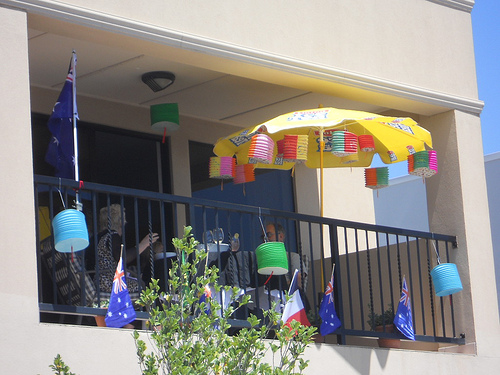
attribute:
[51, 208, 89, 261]
decoration — blue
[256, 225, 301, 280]
decoration — green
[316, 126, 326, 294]
shaft — yellow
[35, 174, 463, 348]
rail — black